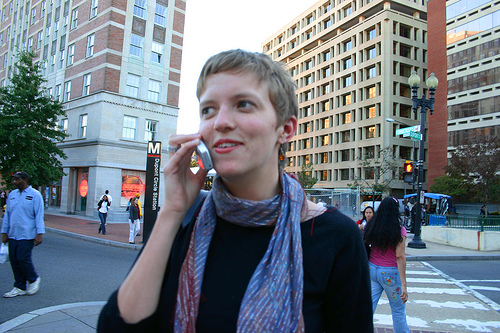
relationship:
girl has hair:
[97, 48, 374, 332] [195, 48, 299, 171]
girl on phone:
[97, 48, 374, 332] [198, 139, 214, 170]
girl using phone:
[97, 48, 374, 332] [198, 139, 214, 170]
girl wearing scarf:
[97, 48, 374, 332] [175, 174, 305, 331]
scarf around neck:
[175, 174, 305, 331] [217, 155, 281, 199]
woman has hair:
[363, 198, 409, 330] [364, 196, 401, 254]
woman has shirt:
[363, 198, 409, 330] [367, 226, 408, 266]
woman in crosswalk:
[363, 198, 409, 330] [372, 260, 499, 331]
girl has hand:
[97, 48, 374, 332] [164, 134, 208, 216]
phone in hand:
[198, 139, 214, 170] [164, 134, 208, 216]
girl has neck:
[97, 48, 374, 332] [217, 155, 281, 199]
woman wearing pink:
[363, 198, 409, 330] [369, 224, 406, 272]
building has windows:
[2, 1, 186, 225] [132, 0, 169, 28]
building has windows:
[2, 1, 186, 225] [127, 33, 165, 65]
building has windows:
[2, 1, 186, 225] [122, 72, 163, 104]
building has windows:
[2, 1, 186, 225] [120, 114, 159, 146]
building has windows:
[262, 1, 446, 201] [299, 44, 335, 89]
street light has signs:
[408, 68, 439, 250] [394, 125, 424, 145]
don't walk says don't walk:
[406, 160, 415, 174] [406, 160, 415, 174]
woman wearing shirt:
[363, 198, 409, 330] [367, 226, 408, 266]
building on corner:
[2, 1, 186, 225] [44, 212, 143, 251]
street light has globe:
[408, 68, 439, 250] [407, 68, 420, 89]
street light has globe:
[408, 68, 439, 250] [426, 72, 440, 93]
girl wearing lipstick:
[97, 48, 374, 332] [210, 137, 243, 154]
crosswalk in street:
[372, 260, 499, 331] [365, 258, 497, 331]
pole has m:
[144, 142, 159, 242] [148, 141, 161, 153]